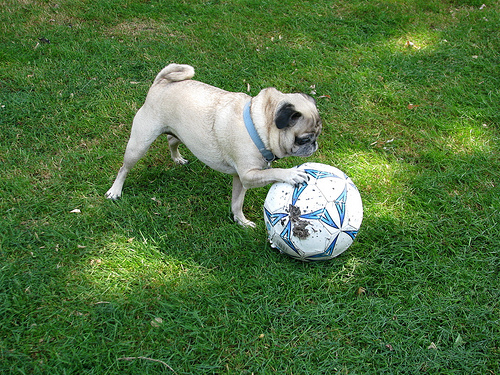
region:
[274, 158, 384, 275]
the ball is white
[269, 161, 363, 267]
the ball has blue diagrams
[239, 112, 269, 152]
the colar is blue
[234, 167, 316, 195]
the foot is on the ball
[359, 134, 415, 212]
light spots are on the grass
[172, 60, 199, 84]
the tail is curled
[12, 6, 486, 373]
the scene is in the park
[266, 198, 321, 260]
the dirt is grey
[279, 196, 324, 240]
dirt is on the ball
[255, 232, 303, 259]
the ball is torn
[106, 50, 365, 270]
a pug is playing soccer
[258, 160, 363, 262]
the soccer ball is punctured and chewed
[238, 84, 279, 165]
the dog has a blue collar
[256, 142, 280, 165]
a metal buckle is on the collar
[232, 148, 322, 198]
the dog has a paw on the soccer ball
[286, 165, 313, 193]
black nails of the dog are on the ball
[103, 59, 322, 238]
the dog has white fur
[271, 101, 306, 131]
the ear is black on the dog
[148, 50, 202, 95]
the dog's tail is curled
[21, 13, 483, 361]
the dog is playing in a yard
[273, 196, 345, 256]
grey dirt on soccer ball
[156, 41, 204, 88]
dog's upturned curled tail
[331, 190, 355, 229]
light blue triangles on soccer ball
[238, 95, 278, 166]
light blue collar on pug dog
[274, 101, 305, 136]
black ear on pug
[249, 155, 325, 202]
dog's paw touching ball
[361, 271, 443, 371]
area of green grass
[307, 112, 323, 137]
wrinkles on pug's forehead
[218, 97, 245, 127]
wrinkles on pugs back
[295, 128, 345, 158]
dog looking intently at soccer ball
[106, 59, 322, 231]
the dog standing on the grass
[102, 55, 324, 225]
the dog standing next to a ball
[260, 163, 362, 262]
the ball on the grass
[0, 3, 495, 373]
the lush green grass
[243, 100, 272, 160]
the blue collar on the dog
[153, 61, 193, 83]
the tail on the dog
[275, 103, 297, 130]
the dog's black ear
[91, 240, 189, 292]
the sun shining on the grass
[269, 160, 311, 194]
the dogs paw on the ball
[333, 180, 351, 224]
the blue shape on the ball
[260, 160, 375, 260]
Ball with design on it.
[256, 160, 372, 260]
Geometric design blue, black on white background.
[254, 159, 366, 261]
Imperfections in the ball.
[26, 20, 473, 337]
Fluffy green grass to play on.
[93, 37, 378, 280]
Pugs paw is on ball.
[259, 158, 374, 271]
Triangles shapes in blue with black outline.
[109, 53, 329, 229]
Small white pug with black eyes and ears.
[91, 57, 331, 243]
Three white feet on the grass.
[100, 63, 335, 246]
Black outline on eyes looks like a robber with mask.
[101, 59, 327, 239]
Blue collar with metal ring.